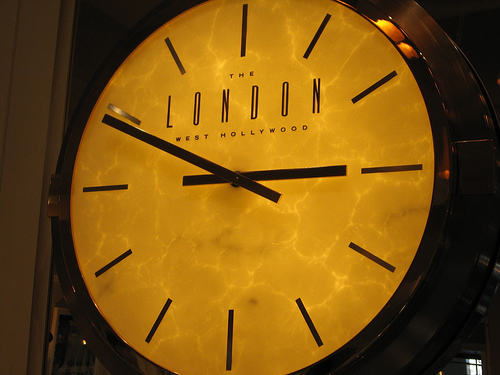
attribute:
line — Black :
[295, 297, 324, 348]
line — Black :
[226, 308, 233, 369]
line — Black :
[347, 241, 394, 271]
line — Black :
[352, 71, 394, 103]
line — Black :
[239, 4, 246, 55]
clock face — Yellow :
[72, 1, 448, 374]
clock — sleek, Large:
[43, 0, 498, 373]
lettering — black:
[155, 71, 328, 146]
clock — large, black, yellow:
[37, 7, 447, 361]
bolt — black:
[204, 167, 264, 197]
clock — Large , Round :
[70, 1, 465, 373]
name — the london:
[162, 77, 323, 127]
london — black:
[163, 77, 323, 127]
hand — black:
[97, 108, 347, 196]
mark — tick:
[294, 296, 324, 347]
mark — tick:
[164, 37, 181, 71]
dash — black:
[223, 307, 237, 368]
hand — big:
[104, 114, 280, 198]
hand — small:
[182, 165, 346, 185]